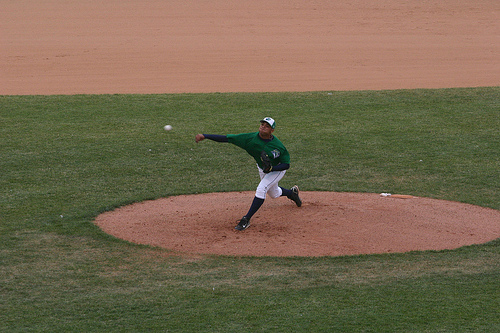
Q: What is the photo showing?
A: It is showing a field.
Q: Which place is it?
A: It is a field.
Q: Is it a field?
A: Yes, it is a field.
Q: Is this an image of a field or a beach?
A: It is showing a field.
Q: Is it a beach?
A: No, it is a field.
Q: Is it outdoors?
A: Yes, it is outdoors.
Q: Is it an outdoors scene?
A: Yes, it is outdoors.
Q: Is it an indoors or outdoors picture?
A: It is outdoors.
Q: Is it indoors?
A: No, it is outdoors.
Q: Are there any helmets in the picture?
A: No, there are no helmets.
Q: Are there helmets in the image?
A: No, there are no helmets.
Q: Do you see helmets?
A: No, there are no helmets.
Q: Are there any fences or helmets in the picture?
A: No, there are no helmets or fences.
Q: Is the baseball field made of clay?
A: Yes, the field is made of clay.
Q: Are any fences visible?
A: No, there are no fences.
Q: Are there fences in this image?
A: No, there are no fences.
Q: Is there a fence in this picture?
A: No, there are no fences.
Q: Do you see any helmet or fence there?
A: No, there are no fences or helmets.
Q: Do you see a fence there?
A: No, there are no fences.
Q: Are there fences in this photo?
A: No, there are no fences.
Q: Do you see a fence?
A: No, there are no fences.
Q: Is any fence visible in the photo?
A: No, there are no fences.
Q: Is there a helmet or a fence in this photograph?
A: No, there are no fences or helmets.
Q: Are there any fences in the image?
A: No, there are no fences.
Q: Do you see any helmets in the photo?
A: No, there are no helmets.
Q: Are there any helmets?
A: No, there are no helmets.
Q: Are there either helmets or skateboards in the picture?
A: No, there are no helmets or skateboards.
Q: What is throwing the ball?
A: The pitcher is throwing the ball.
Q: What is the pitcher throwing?
A: The pitcher is throwing the ball.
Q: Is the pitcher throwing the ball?
A: Yes, the pitcher is throwing the ball.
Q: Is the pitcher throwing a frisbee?
A: No, the pitcher is throwing the ball.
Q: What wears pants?
A: The pitcher wears pants.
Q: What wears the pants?
A: The pitcher wears pants.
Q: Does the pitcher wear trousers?
A: Yes, the pitcher wears trousers.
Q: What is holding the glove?
A: The pitcher is holding the glove.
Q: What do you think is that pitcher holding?
A: The pitcher is holding the glove.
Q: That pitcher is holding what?
A: The pitcher is holding the glove.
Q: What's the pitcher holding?
A: The pitcher is holding the glove.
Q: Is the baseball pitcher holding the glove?
A: Yes, the pitcher is holding the glove.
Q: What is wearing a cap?
A: The pitcher is wearing a cap.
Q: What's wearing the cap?
A: The pitcher is wearing a cap.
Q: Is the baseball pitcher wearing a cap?
A: Yes, the pitcher is wearing a cap.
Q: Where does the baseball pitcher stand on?
A: The pitcher stands on the field.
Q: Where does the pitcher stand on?
A: The pitcher stands on the field.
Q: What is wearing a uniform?
A: The pitcher is wearing a uniform.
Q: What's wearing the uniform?
A: The pitcher is wearing a uniform.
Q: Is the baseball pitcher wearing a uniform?
A: Yes, the pitcher is wearing a uniform.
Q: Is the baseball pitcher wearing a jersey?
A: No, the pitcher is wearing a uniform.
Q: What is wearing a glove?
A: The pitcher is wearing a glove.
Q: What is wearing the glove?
A: The pitcher is wearing a glove.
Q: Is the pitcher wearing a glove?
A: Yes, the pitcher is wearing a glove.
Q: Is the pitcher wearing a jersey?
A: No, the pitcher is wearing a glove.